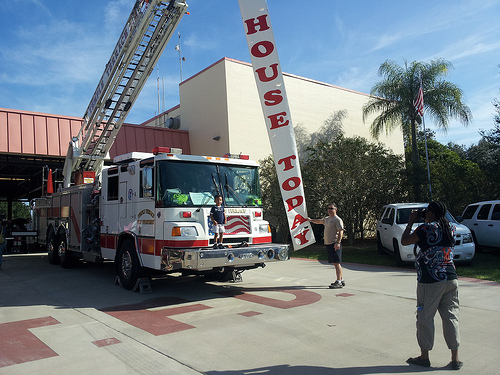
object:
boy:
[210, 193, 228, 248]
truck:
[30, 146, 287, 290]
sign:
[239, 5, 317, 251]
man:
[307, 204, 345, 288]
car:
[375, 201, 477, 264]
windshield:
[157, 159, 261, 205]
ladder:
[63, 0, 187, 175]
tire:
[114, 233, 142, 289]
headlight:
[181, 225, 199, 237]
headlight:
[259, 224, 270, 233]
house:
[243, 14, 289, 131]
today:
[276, 154, 313, 245]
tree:
[361, 55, 472, 200]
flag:
[413, 87, 424, 116]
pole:
[419, 77, 432, 203]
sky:
[0, 0, 500, 143]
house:
[0, 54, 410, 252]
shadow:
[202, 360, 457, 373]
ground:
[0, 250, 500, 375]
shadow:
[226, 283, 335, 293]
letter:
[243, 14, 270, 35]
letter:
[251, 40, 273, 58]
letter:
[256, 62, 279, 84]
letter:
[263, 88, 283, 107]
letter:
[266, 112, 290, 131]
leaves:
[399, 88, 401, 90]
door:
[135, 157, 156, 238]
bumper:
[181, 242, 290, 272]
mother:
[399, 200, 465, 370]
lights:
[152, 146, 172, 155]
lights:
[239, 154, 249, 160]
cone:
[46, 169, 54, 193]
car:
[459, 198, 499, 250]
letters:
[1, 314, 62, 367]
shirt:
[320, 215, 345, 245]